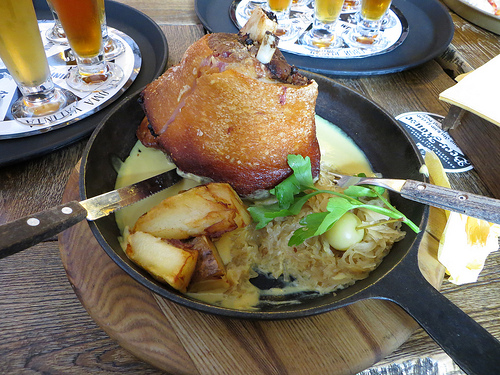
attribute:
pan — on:
[56, 50, 498, 373]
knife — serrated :
[1, 169, 183, 259]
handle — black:
[367, 224, 495, 372]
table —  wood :
[7, 260, 62, 374]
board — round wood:
[65, 139, 457, 374]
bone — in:
[235, 7, 284, 64]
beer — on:
[11, 24, 139, 105]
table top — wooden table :
[0, 241, 115, 373]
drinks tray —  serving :
[278, 3, 393, 35]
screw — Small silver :
[443, 180, 473, 219]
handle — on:
[1, 200, 88, 257]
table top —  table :
[1, 1, 497, 372]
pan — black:
[61, 51, 461, 328]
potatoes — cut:
[113, 177, 257, 294]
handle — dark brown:
[1, 195, 88, 272]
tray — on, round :
[1, 1, 169, 171]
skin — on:
[195, 76, 254, 114]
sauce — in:
[131, 146, 156, 180]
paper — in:
[45, 42, 71, 82]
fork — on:
[314, 157, 482, 239]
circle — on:
[24, 212, 49, 231]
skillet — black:
[99, 59, 445, 313]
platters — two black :
[3, 4, 470, 165]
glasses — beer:
[3, 4, 110, 113]